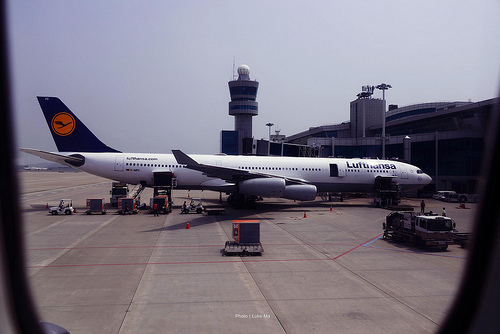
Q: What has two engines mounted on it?
A: Wing of plane.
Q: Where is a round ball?
A: On top of air traffic control tower.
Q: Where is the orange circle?
A: Tail of the plane.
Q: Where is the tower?
A: Behind plane.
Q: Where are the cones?
A: Around the plane.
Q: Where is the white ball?
A: On top of the tower.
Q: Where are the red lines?
A: On the ground.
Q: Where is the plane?
A: On tarmac.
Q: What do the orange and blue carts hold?
A: Luggage.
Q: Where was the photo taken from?
A: Plane window.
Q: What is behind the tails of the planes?
A: Runway.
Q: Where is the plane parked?
A: At an airport.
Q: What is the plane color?
A: White.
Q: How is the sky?
A: Clear with no clouds.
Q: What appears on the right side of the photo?
A: A vehicle.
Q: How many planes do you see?
A: One.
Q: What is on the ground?
A: Cement.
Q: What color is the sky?
A: Blue.